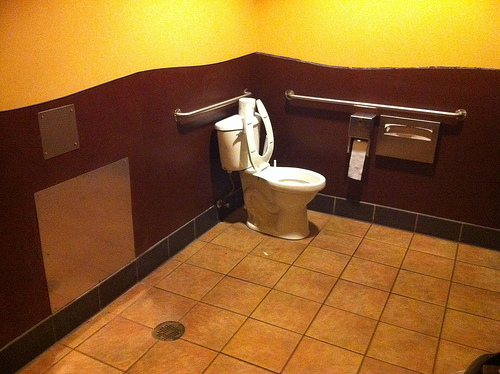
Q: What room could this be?
A: It is a bathroom.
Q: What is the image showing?
A: It is showing a bathroom.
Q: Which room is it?
A: It is a bathroom.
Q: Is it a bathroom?
A: Yes, it is a bathroom.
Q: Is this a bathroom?
A: Yes, it is a bathroom.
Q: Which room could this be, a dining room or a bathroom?
A: It is a bathroom.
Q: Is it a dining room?
A: No, it is a bathroom.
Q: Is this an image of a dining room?
A: No, the picture is showing a bathroom.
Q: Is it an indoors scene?
A: Yes, it is indoors.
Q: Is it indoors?
A: Yes, it is indoors.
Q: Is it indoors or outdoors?
A: It is indoors.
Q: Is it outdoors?
A: No, it is indoors.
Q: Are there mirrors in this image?
A: No, there are no mirrors.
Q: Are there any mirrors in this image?
A: No, there are no mirrors.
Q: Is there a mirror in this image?
A: No, there are no mirrors.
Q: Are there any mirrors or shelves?
A: No, there are no mirrors or shelves.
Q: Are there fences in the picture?
A: No, there are no fences.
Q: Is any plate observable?
A: Yes, there is a plate.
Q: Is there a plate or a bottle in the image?
A: Yes, there is a plate.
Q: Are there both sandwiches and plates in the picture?
A: No, there is a plate but no sandwiches.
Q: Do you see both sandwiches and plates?
A: No, there is a plate but no sandwiches.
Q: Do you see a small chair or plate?
A: Yes, there is a small plate.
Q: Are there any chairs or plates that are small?
A: Yes, the plate is small.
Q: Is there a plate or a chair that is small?
A: Yes, the plate is small.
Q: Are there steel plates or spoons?
A: Yes, there is a steel plate.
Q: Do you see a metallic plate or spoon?
A: Yes, there is a metal plate.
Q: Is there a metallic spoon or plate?
A: Yes, there is a metal plate.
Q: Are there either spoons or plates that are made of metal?
A: Yes, the plate is made of metal.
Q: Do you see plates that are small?
A: Yes, there is a small plate.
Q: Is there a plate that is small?
A: Yes, there is a plate that is small.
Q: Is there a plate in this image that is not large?
A: Yes, there is a small plate.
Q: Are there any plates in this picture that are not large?
A: Yes, there is a small plate.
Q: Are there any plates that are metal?
A: Yes, there is a metal plate.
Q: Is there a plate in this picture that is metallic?
A: Yes, there is a plate that is metallic.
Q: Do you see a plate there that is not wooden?
A: Yes, there is a metallic plate.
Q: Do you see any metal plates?
A: Yes, there is a plate that is made of metal.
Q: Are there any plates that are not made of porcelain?
A: Yes, there is a plate that is made of metal.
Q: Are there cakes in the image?
A: No, there are no cakes.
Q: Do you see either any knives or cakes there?
A: No, there are no cakes or knives.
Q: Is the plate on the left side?
A: Yes, the plate is on the left of the image.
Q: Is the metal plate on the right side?
A: No, the plate is on the left of the image.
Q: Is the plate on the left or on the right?
A: The plate is on the left of the image.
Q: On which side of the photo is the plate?
A: The plate is on the left of the image.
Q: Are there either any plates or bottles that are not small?
A: No, there is a plate but it is small.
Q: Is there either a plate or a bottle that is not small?
A: No, there is a plate but it is small.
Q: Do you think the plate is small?
A: Yes, the plate is small.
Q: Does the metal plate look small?
A: Yes, the plate is small.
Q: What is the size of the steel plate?
A: The plate is small.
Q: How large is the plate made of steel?
A: The plate is small.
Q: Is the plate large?
A: No, the plate is small.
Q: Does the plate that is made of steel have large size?
A: No, the plate is small.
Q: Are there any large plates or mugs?
A: No, there is a plate but it is small.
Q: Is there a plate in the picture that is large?
A: No, there is a plate but it is small.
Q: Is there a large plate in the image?
A: No, there is a plate but it is small.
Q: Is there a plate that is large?
A: No, there is a plate but it is small.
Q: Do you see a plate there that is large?
A: No, there is a plate but it is small.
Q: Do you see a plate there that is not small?
A: No, there is a plate but it is small.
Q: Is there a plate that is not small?
A: No, there is a plate but it is small.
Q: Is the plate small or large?
A: The plate is small.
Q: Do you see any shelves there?
A: No, there are no shelves.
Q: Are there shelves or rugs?
A: No, there are no shelves or rugs.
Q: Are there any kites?
A: No, there are no kites.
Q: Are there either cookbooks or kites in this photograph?
A: No, there are no kites or cookbooks.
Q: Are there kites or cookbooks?
A: No, there are no kites or cookbooks.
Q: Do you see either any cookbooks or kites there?
A: No, there are no kites or cookbooks.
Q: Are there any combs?
A: No, there are no combs.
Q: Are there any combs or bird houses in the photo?
A: No, there are no combs or bird houses.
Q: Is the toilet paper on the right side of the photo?
A: Yes, the toilet paper is on the right of the image.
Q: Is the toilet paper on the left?
A: No, the toilet paper is on the right of the image.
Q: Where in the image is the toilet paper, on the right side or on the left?
A: The toilet paper is on the right of the image.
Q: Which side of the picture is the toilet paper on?
A: The toilet paper is on the right of the image.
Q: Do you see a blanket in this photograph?
A: No, there are no blankets.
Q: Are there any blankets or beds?
A: No, there are no blankets or beds.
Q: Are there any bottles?
A: No, there are no bottles.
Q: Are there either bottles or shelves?
A: No, there are no bottles or shelves.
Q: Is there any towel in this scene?
A: No, there are no towels.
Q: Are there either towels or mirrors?
A: No, there are no towels or mirrors.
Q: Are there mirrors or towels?
A: No, there are no towels or mirrors.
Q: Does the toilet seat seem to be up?
A: Yes, the toilet seat is up.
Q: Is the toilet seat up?
A: Yes, the toilet seat is up.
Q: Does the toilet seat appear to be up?
A: Yes, the toilet seat is up.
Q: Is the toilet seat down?
A: No, the toilet seat is up.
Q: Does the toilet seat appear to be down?
A: No, the toilet seat is up.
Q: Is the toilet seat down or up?
A: The toilet seat is up.